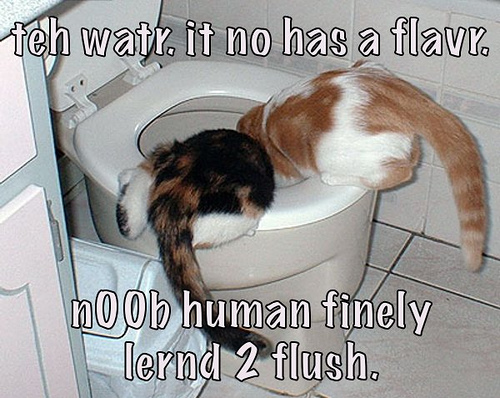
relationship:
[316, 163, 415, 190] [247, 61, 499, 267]
paws of a cat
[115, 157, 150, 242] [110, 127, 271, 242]
paw on a cat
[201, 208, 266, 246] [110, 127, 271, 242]
paw on a cat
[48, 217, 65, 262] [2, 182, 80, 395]
door hinges on a door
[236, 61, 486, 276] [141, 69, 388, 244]
cat leaning into bowl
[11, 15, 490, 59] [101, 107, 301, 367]
letters for meme of cat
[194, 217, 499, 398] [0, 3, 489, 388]
bathroom floor in bathroom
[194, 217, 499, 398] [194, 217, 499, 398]
bathroom floor on bathroom floor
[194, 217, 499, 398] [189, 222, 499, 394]
bathroom floor in bathroom floor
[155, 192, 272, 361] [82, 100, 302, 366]
cat tail on cat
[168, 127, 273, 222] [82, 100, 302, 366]
back of cat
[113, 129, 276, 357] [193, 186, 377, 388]
cat drinking out of toilet bowl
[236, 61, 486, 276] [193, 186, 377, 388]
cat drinking out of toilet bowl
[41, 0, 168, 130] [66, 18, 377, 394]
bowl lid of a toilet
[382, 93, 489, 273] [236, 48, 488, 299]
cat tail of cat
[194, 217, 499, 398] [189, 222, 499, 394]
bathroom floor on bathroom floor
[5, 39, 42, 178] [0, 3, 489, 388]
drawer in bathroom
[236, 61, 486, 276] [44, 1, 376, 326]
cat with head in toilet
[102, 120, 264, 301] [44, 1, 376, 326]
cat with head in toilet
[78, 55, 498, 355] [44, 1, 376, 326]
cat's heads in a toilet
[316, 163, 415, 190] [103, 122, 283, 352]
paws on a cat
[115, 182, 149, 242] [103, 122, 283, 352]
paw on a cat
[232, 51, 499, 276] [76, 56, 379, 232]
cat on a bowl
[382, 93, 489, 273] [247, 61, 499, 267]
cat tail on a cat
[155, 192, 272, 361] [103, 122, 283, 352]
cat tail on a cat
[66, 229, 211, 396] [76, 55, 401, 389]
trash can near a toilet